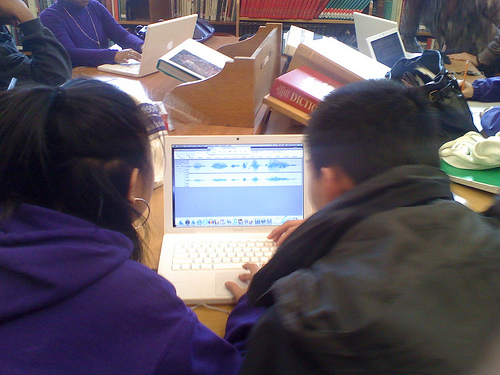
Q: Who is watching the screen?
A: Girl and boy.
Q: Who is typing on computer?
A: The boy.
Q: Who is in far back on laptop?
A: Woman in purple shirt.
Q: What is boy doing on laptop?
A: Editing audio files.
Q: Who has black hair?
A: Girl and boy.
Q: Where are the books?
A: On wooden desk.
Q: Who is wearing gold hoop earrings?
A: The girl.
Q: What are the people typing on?
A: Small white laptop.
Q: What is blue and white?
A: The screen.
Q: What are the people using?
A: Laptops.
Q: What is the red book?
A: Dictionary.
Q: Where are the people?
A: Library.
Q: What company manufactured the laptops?
A: Apple.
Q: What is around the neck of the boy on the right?
A: Scarf.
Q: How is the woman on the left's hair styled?
A: Ponytail.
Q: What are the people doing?
A: Studying.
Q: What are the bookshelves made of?
A: Wood.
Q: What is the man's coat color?
A: Grey.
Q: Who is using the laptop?
A: Woman and man.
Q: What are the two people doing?
A: Sharing a computer.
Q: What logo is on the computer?
A: Apple.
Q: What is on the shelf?
A: Books.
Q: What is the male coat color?
A: Brown.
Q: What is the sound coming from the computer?
A: Sound waves.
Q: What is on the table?
A: Four laptops.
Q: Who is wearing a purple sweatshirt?
A: The woman.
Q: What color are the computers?
A: White.